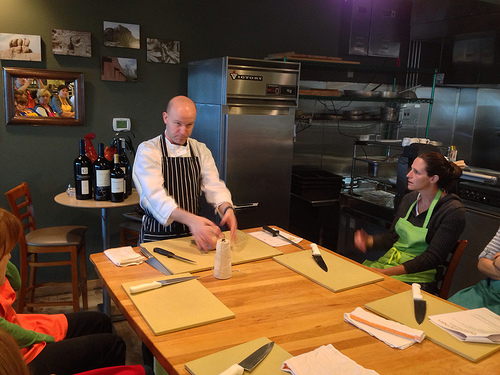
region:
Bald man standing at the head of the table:
[132, 94, 241, 252]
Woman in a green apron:
[355, 146, 470, 293]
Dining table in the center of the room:
[88, 222, 499, 374]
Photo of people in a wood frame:
[0, 64, 90, 130]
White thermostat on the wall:
[110, 114, 132, 135]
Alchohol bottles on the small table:
[69, 124, 138, 205]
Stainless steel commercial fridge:
[182, 51, 305, 240]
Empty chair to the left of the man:
[2, 179, 94, 317]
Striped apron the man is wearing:
[137, 131, 204, 244]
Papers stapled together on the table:
[426, 302, 499, 348]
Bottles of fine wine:
[72, 138, 132, 203]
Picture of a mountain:
[102, 20, 140, 47]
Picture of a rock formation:
[0, 33, 41, 62]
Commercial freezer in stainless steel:
[185, 54, 300, 236]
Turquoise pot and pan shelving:
[266, 56, 438, 160]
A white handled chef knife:
[410, 282, 427, 327]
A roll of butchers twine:
[212, 236, 233, 280]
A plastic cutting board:
[139, 228, 284, 274]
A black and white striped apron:
[137, 130, 203, 242]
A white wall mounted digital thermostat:
[110, 116, 131, 131]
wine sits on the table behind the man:
[58, 127, 137, 206]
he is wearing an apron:
[147, 127, 204, 240]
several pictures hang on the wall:
[8, 15, 185, 129]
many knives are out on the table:
[126, 218, 475, 374]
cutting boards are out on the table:
[123, 219, 475, 373]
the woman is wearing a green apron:
[373, 197, 452, 269]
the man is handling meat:
[185, 218, 238, 250]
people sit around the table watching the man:
[4, 139, 497, 366]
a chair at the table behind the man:
[8, 176, 95, 312]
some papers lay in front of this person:
[428, 303, 498, 353]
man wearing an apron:
[115, 92, 245, 250]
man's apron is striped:
[136, 137, 211, 242]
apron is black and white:
[143, 135, 212, 243]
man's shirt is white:
[126, 125, 242, 238]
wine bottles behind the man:
[61, 137, 148, 209]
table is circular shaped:
[38, 181, 153, 219]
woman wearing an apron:
[354, 148, 467, 290]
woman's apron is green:
[351, 178, 445, 283]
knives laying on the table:
[88, 221, 487, 371]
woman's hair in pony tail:
[395, 137, 467, 196]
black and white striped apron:
[136, 129, 207, 247]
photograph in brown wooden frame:
[0, 62, 87, 131]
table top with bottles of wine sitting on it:
[48, 135, 145, 212]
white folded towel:
[99, 240, 149, 268]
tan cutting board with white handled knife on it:
[117, 270, 239, 339]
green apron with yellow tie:
[355, 186, 440, 287]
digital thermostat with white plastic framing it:
[110, 114, 133, 134]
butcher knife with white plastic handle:
[407, 279, 432, 327]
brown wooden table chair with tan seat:
[2, 176, 91, 316]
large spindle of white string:
[207, 232, 236, 282]